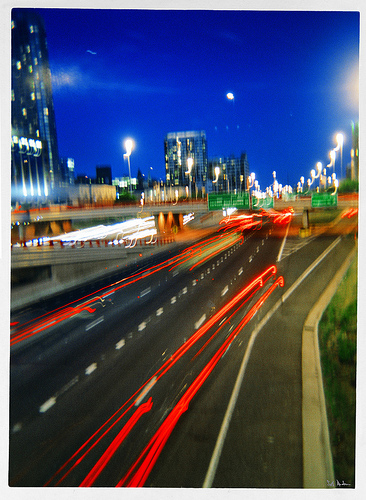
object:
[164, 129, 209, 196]
building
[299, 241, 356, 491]
edge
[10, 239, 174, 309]
ramp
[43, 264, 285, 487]
streaks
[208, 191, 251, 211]
sign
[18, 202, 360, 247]
bridge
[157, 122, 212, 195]
grass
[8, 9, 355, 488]
city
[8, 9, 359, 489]
light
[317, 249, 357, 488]
grass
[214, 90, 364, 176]
flying kite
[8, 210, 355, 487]
road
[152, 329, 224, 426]
breaklights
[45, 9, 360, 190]
clouds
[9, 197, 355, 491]
cars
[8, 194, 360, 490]
highway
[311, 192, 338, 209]
sign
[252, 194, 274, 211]
sign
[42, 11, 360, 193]
sky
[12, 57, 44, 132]
windows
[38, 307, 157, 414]
lines